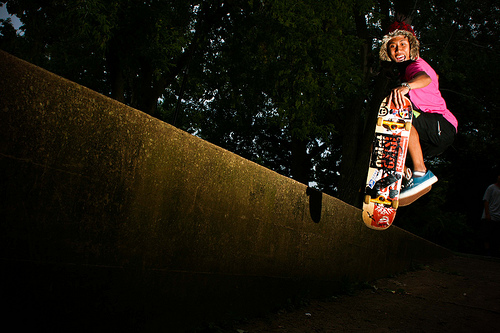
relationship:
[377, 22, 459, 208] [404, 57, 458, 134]
skateboarder wearing shirt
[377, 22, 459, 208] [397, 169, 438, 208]
skateboarder has shoes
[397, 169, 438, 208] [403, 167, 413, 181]
shoes have laces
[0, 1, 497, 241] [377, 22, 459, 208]
trees behind skateboarder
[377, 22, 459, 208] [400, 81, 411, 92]
skateboarder has watch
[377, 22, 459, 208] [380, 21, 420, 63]
skateboarder has hat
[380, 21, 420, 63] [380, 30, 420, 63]
hat has trim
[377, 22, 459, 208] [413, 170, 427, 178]
skateboarder has sock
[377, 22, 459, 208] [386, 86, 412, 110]
skateboarder has hand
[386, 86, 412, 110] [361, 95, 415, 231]
hand gripping stickers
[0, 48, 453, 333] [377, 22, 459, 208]
wall behind skateboarder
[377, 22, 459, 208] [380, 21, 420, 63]
skateboarder wearing hat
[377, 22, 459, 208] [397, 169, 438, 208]
skateboarder wearing shoes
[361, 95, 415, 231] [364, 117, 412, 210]
stickers has wheels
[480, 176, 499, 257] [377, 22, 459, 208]
person watching skateboarder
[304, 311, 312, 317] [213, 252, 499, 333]
trash on ground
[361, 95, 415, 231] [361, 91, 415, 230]
stickers has stickers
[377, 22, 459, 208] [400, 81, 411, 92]
skateboarder wearing watch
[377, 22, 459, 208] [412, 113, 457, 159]
skateboarder wearing shorts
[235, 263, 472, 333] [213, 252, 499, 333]
leaves on ground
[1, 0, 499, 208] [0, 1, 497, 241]
sky behind trees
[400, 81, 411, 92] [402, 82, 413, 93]
watch on wrist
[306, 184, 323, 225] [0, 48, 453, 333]
shadow on wall